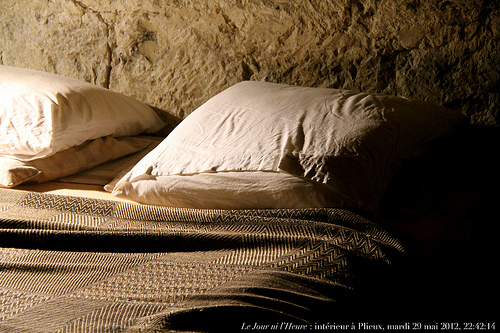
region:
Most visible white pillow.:
[105, 79, 471, 206]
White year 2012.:
[439, 321, 459, 331]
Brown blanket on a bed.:
[0, 184, 404, 332]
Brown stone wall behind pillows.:
[0, 1, 498, 121]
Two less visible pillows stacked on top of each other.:
[0, 61, 162, 192]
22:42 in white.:
[462, 320, 486, 330]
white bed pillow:
[96, 72, 416, 196]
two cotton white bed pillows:
[8, 63, 160, 185]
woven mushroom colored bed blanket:
[5, 187, 359, 323]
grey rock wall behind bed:
[1, 7, 498, 141]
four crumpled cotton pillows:
[3, 63, 401, 213]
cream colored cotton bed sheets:
[35, 133, 415, 203]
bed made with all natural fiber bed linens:
[3, 65, 416, 326]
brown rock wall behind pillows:
[2, 6, 497, 143]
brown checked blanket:
[1, 183, 386, 324]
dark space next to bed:
[303, 152, 483, 317]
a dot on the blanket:
[143, 292, 150, 300]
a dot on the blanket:
[149, 284, 162, 293]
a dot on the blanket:
[102, 295, 116, 302]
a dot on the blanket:
[156, 290, 169, 300]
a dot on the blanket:
[178, 268, 191, 274]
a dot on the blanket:
[324, 283, 337, 291]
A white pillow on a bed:
[2, 62, 159, 144]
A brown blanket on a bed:
[2, 180, 400, 329]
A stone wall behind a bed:
[3, 3, 498, 104]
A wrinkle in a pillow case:
[272, 120, 317, 160]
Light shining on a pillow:
[7, 88, 65, 140]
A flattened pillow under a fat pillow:
[4, 143, 149, 178]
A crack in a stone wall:
[75, 5, 120, 87]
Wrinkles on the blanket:
[243, 270, 345, 325]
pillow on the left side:
[3, 75, 165, 144]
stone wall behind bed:
[55, 12, 325, 59]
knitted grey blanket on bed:
[28, 213, 312, 331]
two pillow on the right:
[119, 93, 361, 235]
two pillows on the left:
[1, 13, 183, 200]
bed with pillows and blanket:
[32, 77, 412, 331]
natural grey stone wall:
[65, 14, 404, 63]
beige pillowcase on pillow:
[133, 178, 328, 214]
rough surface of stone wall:
[1, 0, 496, 142]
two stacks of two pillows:
[1, 62, 430, 206]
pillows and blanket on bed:
[0, 66, 432, 331]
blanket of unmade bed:
[1, 187, 406, 331]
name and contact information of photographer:
[238, 319, 496, 331]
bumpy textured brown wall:
[55, 2, 240, 71]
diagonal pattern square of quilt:
[65, 301, 170, 331]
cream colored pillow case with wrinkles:
[168, 71, 386, 164]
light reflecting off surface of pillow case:
[1, 78, 52, 155]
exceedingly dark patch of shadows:
[419, 134, 494, 315]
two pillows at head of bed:
[0, 58, 421, 213]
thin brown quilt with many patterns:
[3, 189, 386, 330]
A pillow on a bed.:
[128, 55, 463, 186]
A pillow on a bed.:
[109, 161, 359, 220]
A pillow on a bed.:
[0, 72, 171, 158]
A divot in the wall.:
[241, 62, 254, 79]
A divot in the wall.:
[250, 58, 260, 69]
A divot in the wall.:
[374, 48, 401, 88]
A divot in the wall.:
[344, 60, 359, 83]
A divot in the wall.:
[356, 7, 372, 27]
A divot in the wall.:
[435, 60, 461, 89]